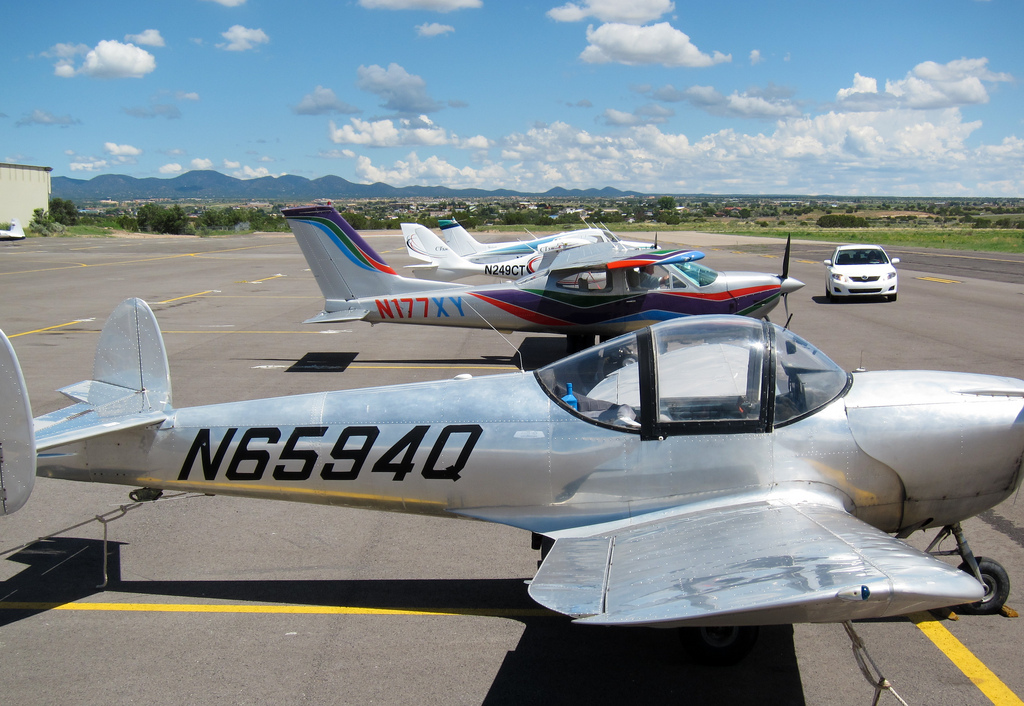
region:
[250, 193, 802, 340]
silver plane with number n177xy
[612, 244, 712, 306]
pilot in cockpit of plane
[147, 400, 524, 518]
black numbers on tail of plane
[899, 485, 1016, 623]
front wheel of plane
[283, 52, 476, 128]
grey clouds in blue sky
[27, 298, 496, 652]
yellow strip under silver plane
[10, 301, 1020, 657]
the plane is silver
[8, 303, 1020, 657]
the plane is on the ground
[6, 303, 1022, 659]
the plane is small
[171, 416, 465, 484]
the plane has numbers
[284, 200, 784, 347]
the plane has stripes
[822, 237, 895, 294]
the car is white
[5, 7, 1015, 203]
the sky is cloudy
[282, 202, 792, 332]
SMALL PLANE SITTING ON TARMAC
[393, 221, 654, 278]
SMALL PLANE SITTING ON TARMAC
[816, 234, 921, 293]
WHITE CAR SITTING ON TARMAC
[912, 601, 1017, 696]
YELLOW LINES PAINTED ON TARMAC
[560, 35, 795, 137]
WHITE CLOUDS IN BLUE SKY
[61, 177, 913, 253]
GREEN VEGETATION AROUND AIRPORT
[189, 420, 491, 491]
BLACK WRITING ON PLANE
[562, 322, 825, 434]
GLASS COCKPIT OF PLANE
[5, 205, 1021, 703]
planes are parked on the airport tarmac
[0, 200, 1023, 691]
planes are tethered to the tarmac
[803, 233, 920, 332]
a car is on the tarmac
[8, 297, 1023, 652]
the single engine plane is silver in color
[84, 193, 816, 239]
houses are near the airport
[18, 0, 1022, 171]
the blue sky is full of puffy clouds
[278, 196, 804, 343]
the plane has red, black, and blue stripes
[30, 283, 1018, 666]
gray plane parked at airport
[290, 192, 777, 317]
plane parked at airport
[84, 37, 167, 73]
white clouds in blue sky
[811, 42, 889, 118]
white clouds in blue sky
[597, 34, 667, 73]
white clouds in blue sky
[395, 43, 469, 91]
white clouds in blue sky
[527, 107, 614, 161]
white clouds in blue sky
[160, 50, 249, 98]
white clouds in blue sky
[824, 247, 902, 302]
a small white car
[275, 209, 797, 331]
a colorful small airplane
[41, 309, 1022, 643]
a silver airplane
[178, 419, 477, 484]
writing on the airplane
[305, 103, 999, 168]
clouds in the sky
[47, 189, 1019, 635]
airplanes lined up on the runway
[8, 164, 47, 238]
a white building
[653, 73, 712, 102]
A cloud in the sky.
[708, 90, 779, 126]
A cloud in the sky.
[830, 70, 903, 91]
A cloud in the sky.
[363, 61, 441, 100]
A cloud in the sky.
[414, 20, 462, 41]
A cloud in the sky.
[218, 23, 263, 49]
A cloud in the sky.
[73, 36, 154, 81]
A cloud in the sky.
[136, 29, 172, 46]
A cloud in the sky.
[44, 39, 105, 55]
A cloud in the sky.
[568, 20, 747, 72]
A cloud in the sky.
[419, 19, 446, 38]
A cloud in the sky.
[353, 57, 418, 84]
A cloud in the sky.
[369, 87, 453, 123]
A cloud in the sky.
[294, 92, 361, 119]
A cloud in the sky.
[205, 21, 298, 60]
A cloud in the sky.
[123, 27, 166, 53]
A cloud in the sky.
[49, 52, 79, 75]
A cloud in the sky.